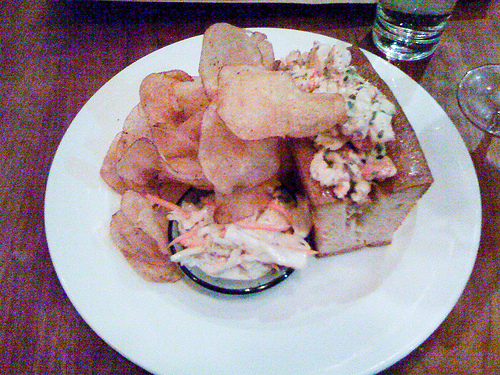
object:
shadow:
[463, 149, 498, 342]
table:
[4, 2, 495, 372]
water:
[372, 3, 447, 58]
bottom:
[456, 64, 498, 140]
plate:
[39, 14, 490, 375]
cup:
[369, 1, 461, 62]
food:
[92, 14, 445, 303]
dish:
[164, 174, 310, 297]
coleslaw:
[175, 196, 299, 276]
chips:
[100, 23, 337, 215]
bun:
[280, 42, 435, 259]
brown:
[4, 6, 101, 81]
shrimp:
[308, 142, 348, 187]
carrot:
[170, 193, 232, 246]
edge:
[36, 109, 70, 315]